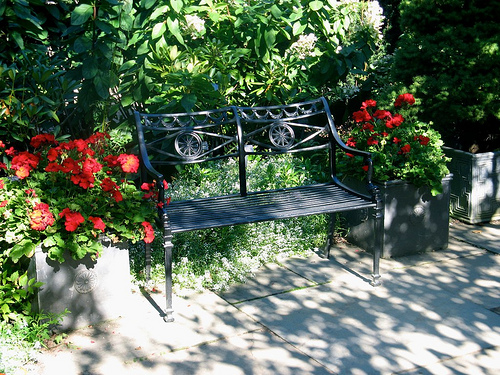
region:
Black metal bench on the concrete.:
[131, 96, 384, 323]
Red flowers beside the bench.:
[2, 130, 152, 264]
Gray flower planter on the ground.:
[342, 157, 457, 257]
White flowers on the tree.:
[287, 30, 319, 61]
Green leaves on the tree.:
[67, 3, 125, 101]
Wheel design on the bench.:
[171, 130, 201, 157]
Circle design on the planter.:
[72, 268, 98, 293]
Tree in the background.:
[390, 0, 495, 145]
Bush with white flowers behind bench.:
[152, 157, 338, 267]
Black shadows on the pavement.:
[27, 248, 498, 374]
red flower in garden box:
[11, 149, 42, 179]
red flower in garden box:
[134, 211, 162, 254]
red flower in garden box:
[27, 197, 49, 232]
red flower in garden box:
[59, 206, 89, 238]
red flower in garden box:
[116, 149, 144, 174]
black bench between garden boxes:
[122, 93, 407, 281]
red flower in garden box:
[401, 143, 409, 151]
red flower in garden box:
[416, 130, 439, 151]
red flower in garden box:
[389, 115, 405, 128]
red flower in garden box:
[396, 85, 418, 115]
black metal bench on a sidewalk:
[138, 89, 395, 277]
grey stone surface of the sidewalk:
[292, 300, 456, 373]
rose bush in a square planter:
[342, 98, 455, 258]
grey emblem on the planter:
[62, 265, 102, 294]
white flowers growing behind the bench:
[157, 153, 325, 273]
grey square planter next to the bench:
[21, 232, 139, 328]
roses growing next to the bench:
[1, 90, 443, 240]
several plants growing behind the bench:
[19, 3, 348, 108]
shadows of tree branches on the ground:
[166, 270, 480, 371]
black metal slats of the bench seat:
[173, 194, 329, 219]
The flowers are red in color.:
[353, 92, 418, 128]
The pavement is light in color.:
[307, 311, 398, 359]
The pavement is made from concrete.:
[298, 303, 380, 355]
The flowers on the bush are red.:
[26, 133, 115, 194]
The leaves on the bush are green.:
[61, 186, 141, 240]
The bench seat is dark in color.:
[196, 197, 294, 218]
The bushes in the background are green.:
[107, 14, 235, 74]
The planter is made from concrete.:
[62, 267, 107, 308]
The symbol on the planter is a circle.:
[71, 266, 103, 296]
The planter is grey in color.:
[405, 197, 436, 239]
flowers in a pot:
[375, 133, 435, 165]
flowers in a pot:
[347, 90, 399, 135]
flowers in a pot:
[30, 196, 115, 246]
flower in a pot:
[131, 208, 156, 240]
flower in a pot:
[11, 190, 49, 240]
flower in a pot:
[15, 145, 45, 185]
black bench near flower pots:
[170, 95, 395, 326]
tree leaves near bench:
[115, 30, 240, 95]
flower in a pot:
[25, 130, 60, 150]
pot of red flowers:
[384, 170, 456, 270]